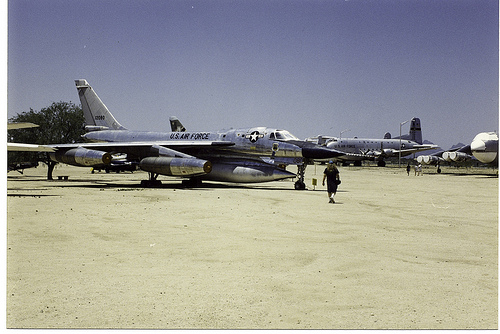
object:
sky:
[7, 0, 499, 150]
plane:
[7, 78, 347, 189]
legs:
[330, 183, 338, 204]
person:
[321, 159, 342, 204]